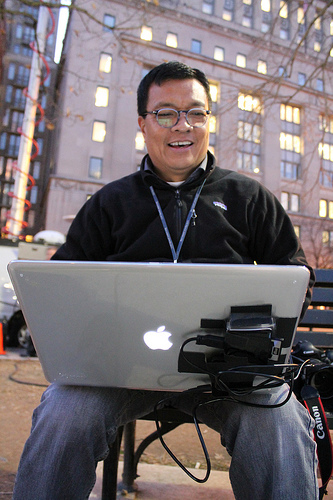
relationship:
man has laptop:
[13, 63, 320, 500] [5, 255, 310, 396]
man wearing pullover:
[13, 63, 320, 500] [49, 153, 314, 286]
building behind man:
[2, 1, 331, 268] [13, 63, 320, 500]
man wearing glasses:
[13, 63, 320, 500] [145, 104, 208, 129]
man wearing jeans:
[13, 63, 320, 500] [16, 386, 331, 499]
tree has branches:
[20, 5, 331, 268] [273, 0, 331, 118]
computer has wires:
[9, 260, 313, 391] [134, 323, 324, 486]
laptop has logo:
[9, 260, 313, 391] [140, 324, 173, 352]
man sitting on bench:
[13, 63, 320, 500] [302, 265, 331, 374]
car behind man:
[3, 282, 33, 359] [13, 63, 320, 500]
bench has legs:
[302, 265, 331, 374] [101, 410, 182, 500]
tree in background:
[20, 5, 331, 268] [2, 1, 331, 268]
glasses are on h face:
[145, 104, 208, 129] [151, 85, 212, 170]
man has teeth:
[13, 63, 320, 500] [169, 141, 193, 149]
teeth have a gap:
[169, 141, 193, 149] [176, 141, 180, 147]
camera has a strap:
[282, 341, 332, 499] [301, 393, 333, 479]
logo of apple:
[140, 324, 173, 352] [138, 325, 174, 355]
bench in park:
[302, 265, 331, 374] [3, 298, 332, 475]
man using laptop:
[13, 63, 320, 500] [9, 260, 313, 391]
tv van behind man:
[1, 239, 57, 353] [13, 63, 320, 500]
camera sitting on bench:
[282, 341, 332, 499] [302, 265, 331, 374]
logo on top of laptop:
[140, 324, 173, 352] [9, 260, 313, 391]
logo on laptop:
[140, 324, 173, 352] [9, 260, 313, 391]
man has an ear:
[13, 63, 320, 500] [138, 116, 146, 138]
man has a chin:
[13, 63, 320, 500] [163, 151, 203, 176]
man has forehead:
[13, 63, 320, 500] [147, 81, 209, 116]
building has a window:
[2, 1, 331, 268] [237, 92, 261, 116]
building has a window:
[2, 1, 331, 268] [277, 132, 302, 154]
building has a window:
[2, 1, 331, 268] [316, 200, 331, 222]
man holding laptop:
[13, 63, 320, 500] [9, 260, 313, 391]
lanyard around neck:
[143, 183, 212, 261] [144, 151, 211, 185]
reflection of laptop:
[160, 118, 174, 130] [9, 260, 313, 391]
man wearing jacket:
[13, 63, 320, 500] [49, 153, 314, 286]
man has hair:
[13, 63, 320, 500] [135, 61, 213, 121]